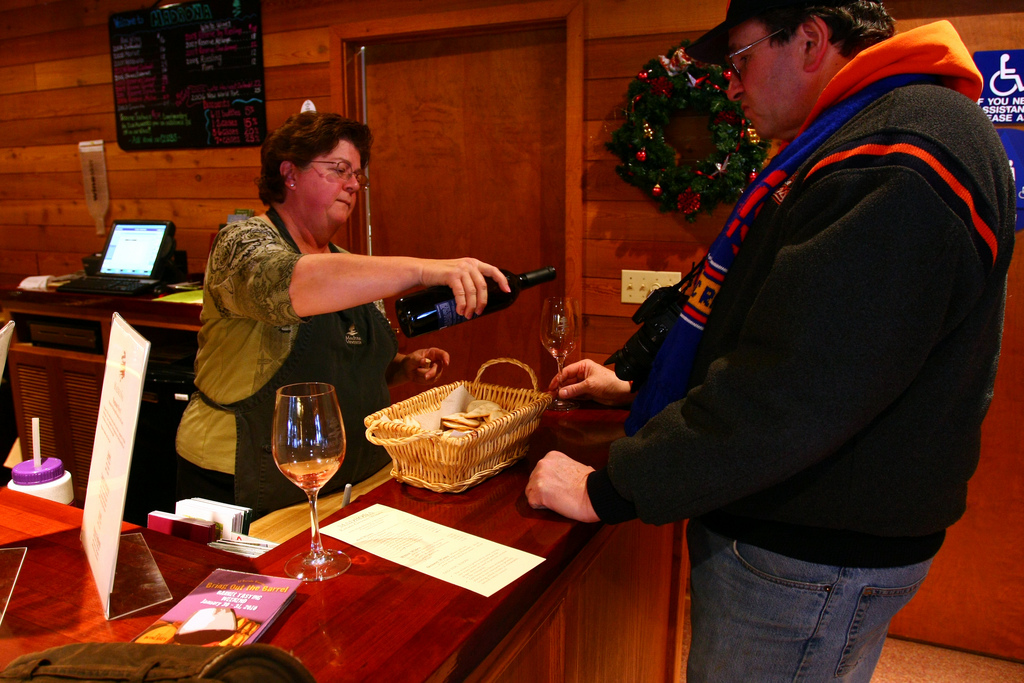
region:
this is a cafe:
[43, 92, 999, 642]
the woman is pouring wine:
[216, 148, 473, 463]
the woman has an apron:
[172, 148, 382, 496]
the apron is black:
[187, 244, 453, 527]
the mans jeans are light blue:
[696, 531, 815, 656]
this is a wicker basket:
[371, 373, 622, 589]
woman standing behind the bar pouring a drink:
[174, 111, 548, 536]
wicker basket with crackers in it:
[363, 356, 553, 492]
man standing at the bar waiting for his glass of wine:
[525, 1, 1015, 679]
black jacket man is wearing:
[585, 71, 1019, 540]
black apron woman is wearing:
[185, 197, 395, 534]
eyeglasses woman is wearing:
[313, 152, 370, 190]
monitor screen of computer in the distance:
[98, 222, 168, 280]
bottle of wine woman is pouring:
[384, 258, 562, 335]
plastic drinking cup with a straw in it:
[5, 413, 76, 506]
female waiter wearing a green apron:
[169, 105, 509, 510]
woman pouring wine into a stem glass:
[172, 108, 564, 502]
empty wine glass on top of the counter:
[266, 377, 353, 586]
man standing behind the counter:
[520, 4, 1018, 673]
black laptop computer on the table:
[51, 215, 179, 301]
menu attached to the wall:
[105, 2, 271, 158]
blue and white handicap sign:
[975, 45, 1021, 128]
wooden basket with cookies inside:
[359, 354, 555, 495]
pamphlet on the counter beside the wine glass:
[136, 559, 308, 648]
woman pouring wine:
[187, 108, 560, 472]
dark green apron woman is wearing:
[164, 207, 422, 508]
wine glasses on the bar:
[269, 286, 580, 566]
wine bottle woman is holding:
[404, 240, 553, 340]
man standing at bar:
[614, 4, 1004, 678]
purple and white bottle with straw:
[10, 414, 75, 513]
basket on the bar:
[361, 339, 551, 496]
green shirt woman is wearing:
[162, 199, 388, 465]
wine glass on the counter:
[268, 402, 368, 590]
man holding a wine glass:
[528, 293, 587, 410]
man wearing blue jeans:
[663, 502, 933, 677]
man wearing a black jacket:
[653, 72, 977, 576]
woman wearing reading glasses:
[288, 148, 368, 188]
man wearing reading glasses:
[707, 37, 768, 82]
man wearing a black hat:
[667, 0, 807, 63]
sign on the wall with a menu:
[95, 3, 288, 171]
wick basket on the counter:
[350, 323, 570, 516]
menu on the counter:
[63, 304, 177, 628]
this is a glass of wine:
[252, 348, 388, 627]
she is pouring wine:
[187, 86, 489, 565]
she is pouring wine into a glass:
[132, 40, 605, 590]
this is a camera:
[599, 239, 815, 470]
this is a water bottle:
[5, 395, 95, 532]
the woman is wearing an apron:
[164, 94, 589, 546]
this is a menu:
[132, 546, 345, 680]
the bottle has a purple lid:
[5, 391, 101, 548]